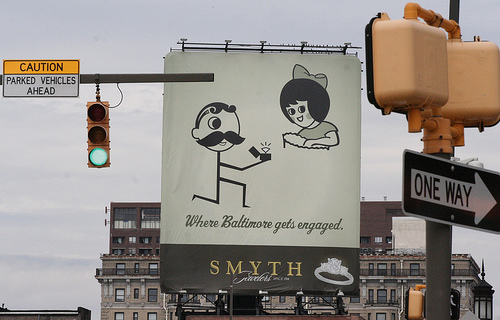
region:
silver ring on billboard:
[288, 222, 378, 293]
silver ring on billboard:
[282, 240, 367, 278]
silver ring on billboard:
[242, 230, 347, 308]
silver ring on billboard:
[287, 240, 354, 311]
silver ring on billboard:
[308, 250, 375, 291]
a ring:
[318, 233, 367, 307]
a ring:
[321, 197, 363, 284]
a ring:
[332, 213, 377, 283]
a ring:
[290, 177, 337, 288]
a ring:
[307, 135, 374, 296]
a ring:
[311, 235, 336, 311]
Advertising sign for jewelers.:
[160, 48, 364, 300]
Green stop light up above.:
[84, 97, 114, 171]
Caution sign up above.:
[1, 55, 81, 99]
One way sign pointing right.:
[400, 143, 495, 235]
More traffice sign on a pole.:
[358, 4, 498, 159]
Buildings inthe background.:
[95, 188, 497, 318]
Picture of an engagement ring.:
[313, 255, 355, 285]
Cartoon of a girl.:
[275, 61, 342, 153]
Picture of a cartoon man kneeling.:
[181, 98, 278, 216]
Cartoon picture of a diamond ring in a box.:
[245, 142, 279, 162]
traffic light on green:
[78, 99, 113, 169]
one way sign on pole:
[410, 151, 492, 231]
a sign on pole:
[3, 55, 80, 103]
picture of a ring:
[302, 245, 364, 290]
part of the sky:
[29, 142, 70, 209]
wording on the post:
[177, 208, 354, 240]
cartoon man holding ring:
[196, 102, 271, 208]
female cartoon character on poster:
[271, 62, 348, 150]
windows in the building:
[107, 283, 158, 303]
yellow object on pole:
[408, 276, 445, 318]